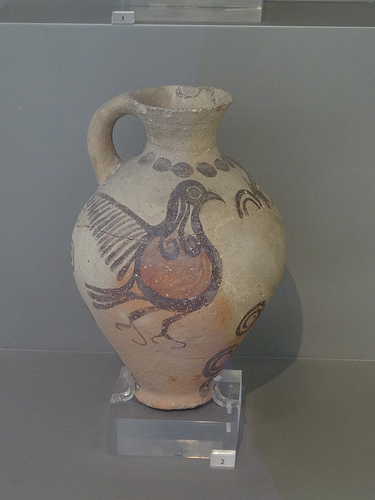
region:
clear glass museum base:
[113, 387, 238, 463]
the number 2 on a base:
[207, 451, 235, 467]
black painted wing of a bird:
[93, 198, 134, 266]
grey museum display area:
[292, 326, 357, 447]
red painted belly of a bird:
[141, 229, 204, 308]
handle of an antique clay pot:
[77, 95, 150, 172]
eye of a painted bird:
[183, 190, 202, 200]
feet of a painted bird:
[106, 316, 199, 357]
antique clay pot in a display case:
[65, 71, 286, 422]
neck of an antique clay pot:
[129, 112, 231, 158]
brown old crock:
[60, 83, 291, 410]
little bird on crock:
[83, 173, 223, 346]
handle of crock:
[87, 94, 136, 178]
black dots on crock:
[135, 148, 236, 174]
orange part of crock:
[98, 266, 245, 406]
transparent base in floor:
[100, 362, 247, 463]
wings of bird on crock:
[85, 191, 147, 281]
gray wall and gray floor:
[4, 1, 369, 493]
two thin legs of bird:
[106, 305, 186, 351]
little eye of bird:
[185, 180, 202, 203]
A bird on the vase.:
[116, 190, 218, 309]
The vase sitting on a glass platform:
[97, 392, 252, 462]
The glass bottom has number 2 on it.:
[203, 444, 237, 468]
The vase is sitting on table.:
[79, 161, 269, 464]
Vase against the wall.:
[76, 80, 257, 430]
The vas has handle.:
[80, 91, 120, 167]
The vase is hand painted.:
[88, 160, 251, 349]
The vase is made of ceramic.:
[84, 85, 288, 350]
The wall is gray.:
[42, 53, 347, 183]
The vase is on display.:
[62, 118, 272, 399]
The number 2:
[207, 444, 245, 475]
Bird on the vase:
[70, 184, 256, 359]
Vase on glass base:
[102, 345, 266, 459]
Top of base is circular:
[113, 60, 253, 130]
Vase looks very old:
[73, 95, 289, 410]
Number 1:
[97, 5, 150, 35]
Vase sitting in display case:
[23, 30, 348, 466]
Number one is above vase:
[91, 3, 178, 55]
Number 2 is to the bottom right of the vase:
[196, 438, 265, 480]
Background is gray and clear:
[1, 54, 79, 187]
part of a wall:
[259, 68, 289, 119]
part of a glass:
[176, 420, 208, 460]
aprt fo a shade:
[239, 363, 273, 442]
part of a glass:
[186, 421, 220, 471]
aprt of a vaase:
[155, 376, 195, 437]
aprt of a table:
[253, 418, 290, 467]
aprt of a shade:
[241, 332, 288, 436]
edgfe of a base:
[164, 421, 204, 482]